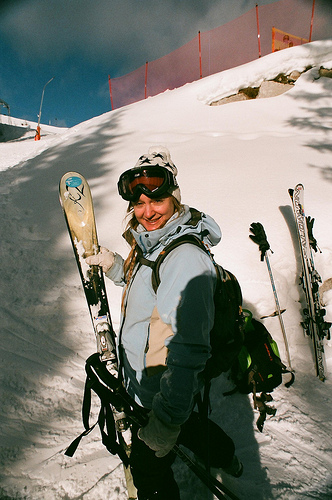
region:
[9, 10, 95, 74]
The sky is blue.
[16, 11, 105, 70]
The sky is cloudy.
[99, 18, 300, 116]
An orange fence.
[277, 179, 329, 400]
A pair of skis.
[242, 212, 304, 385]
A ski pole.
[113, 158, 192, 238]
She is wearing goggles.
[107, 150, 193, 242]
The goggles are black.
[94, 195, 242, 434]
Her top is blue.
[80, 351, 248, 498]
She is holding ski poles.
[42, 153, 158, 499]
She is holding a pair of skis.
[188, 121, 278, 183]
The ground is snow covered.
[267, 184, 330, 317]
The skies are on the ground.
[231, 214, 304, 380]
The gloves are on the poles.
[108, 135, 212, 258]
She is wearing a hat with stars.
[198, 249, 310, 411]
She has a backpack on.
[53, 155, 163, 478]
She is holding her skies.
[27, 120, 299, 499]
The sun is shining.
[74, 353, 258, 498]
She is holding poles.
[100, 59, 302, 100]
The fence is red.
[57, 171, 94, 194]
circular blue line on bottom of ski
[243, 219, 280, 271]
black glove on pole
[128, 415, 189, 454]
green glove on woman's hand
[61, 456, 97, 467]
tiny spots in the snow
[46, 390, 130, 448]
black string around woman's waist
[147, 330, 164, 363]
section of tan shirt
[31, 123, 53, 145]
red pole at top of mountain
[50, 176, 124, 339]
large snow ski in woman's hand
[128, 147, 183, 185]
black and white wool cap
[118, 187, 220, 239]
wide grin on woman's face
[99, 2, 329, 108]
orange netting at the top of a slope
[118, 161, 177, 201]
black goggles on a woman's head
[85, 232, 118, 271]
a white gloved hand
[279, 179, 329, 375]
black and white skis propped in the snow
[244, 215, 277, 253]
a glove on the end of a ski pole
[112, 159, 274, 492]
a woman in a pale blue snow suit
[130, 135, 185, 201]
a white knit hat with navy stars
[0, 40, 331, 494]
a snowy white slope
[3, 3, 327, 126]
a blue cloudy sky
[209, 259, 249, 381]
a grey backpack on a woman's back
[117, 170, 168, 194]
large protective sun goggles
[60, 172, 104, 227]
top part of ski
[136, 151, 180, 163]
black and white cap on head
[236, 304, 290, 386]
part of green backpack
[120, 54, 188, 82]
a red barrier fence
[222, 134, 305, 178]
part of the ski slope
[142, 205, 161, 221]
nose on the woman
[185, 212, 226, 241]
hooded part of jacket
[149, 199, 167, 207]
one of the woman's eyes